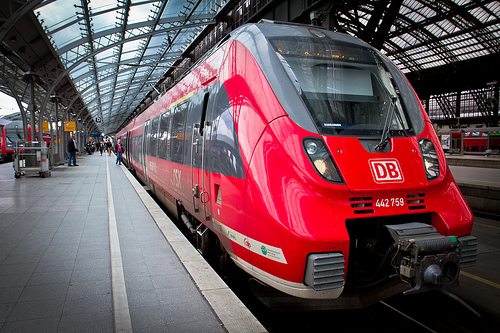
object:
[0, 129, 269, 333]
platform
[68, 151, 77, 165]
jeans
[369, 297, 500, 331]
track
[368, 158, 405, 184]
decal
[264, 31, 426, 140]
wind shield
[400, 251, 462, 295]
connector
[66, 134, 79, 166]
people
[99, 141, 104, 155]
people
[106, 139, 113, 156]
people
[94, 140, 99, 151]
people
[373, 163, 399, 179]
db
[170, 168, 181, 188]
letters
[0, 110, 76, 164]
train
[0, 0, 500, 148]
sun roof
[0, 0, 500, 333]
station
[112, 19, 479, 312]
red train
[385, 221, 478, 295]
motor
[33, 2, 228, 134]
windows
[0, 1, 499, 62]
ceiling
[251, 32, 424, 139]
windshield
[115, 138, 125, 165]
passenger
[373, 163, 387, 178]
letter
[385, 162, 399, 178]
letter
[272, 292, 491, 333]
train tracks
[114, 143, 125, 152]
shirt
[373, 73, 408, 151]
wiper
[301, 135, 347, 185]
light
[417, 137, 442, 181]
head light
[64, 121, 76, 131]
sign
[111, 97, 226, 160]
window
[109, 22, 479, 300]
reflection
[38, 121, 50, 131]
signs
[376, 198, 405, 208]
white numbers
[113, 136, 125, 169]
person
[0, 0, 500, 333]
train station